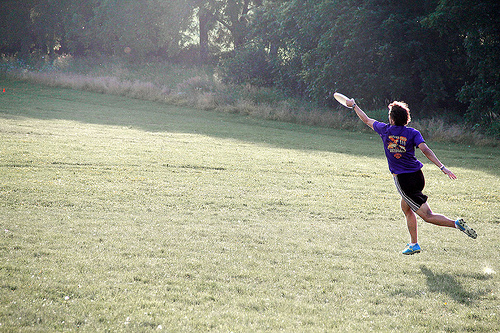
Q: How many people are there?
A: One.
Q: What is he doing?
A: Playing frisbee.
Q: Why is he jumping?
A: To catch frisbee.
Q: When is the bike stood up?
A: No bike.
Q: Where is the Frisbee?
A: In man's hand.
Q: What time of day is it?
A: Daytime.